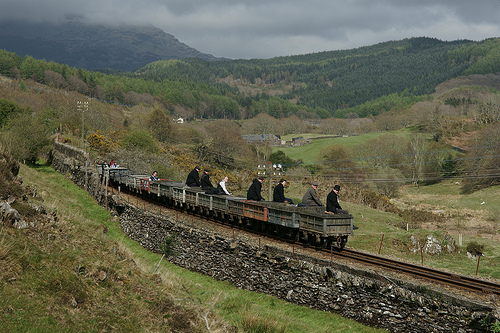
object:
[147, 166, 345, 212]
people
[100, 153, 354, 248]
train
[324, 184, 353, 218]
men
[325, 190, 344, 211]
coats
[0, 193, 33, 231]
rocks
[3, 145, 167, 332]
hillside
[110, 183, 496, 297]
tracks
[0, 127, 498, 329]
field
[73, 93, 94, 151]
lights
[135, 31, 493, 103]
mountains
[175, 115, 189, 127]
house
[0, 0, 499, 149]
background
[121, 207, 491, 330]
wall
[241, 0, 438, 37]
clouds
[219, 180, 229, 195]
sleeve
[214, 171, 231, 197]
passenger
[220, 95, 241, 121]
trees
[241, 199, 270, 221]
cart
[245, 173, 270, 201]
person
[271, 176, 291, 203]
person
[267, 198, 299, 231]
cart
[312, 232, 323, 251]
wheels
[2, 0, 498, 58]
sky